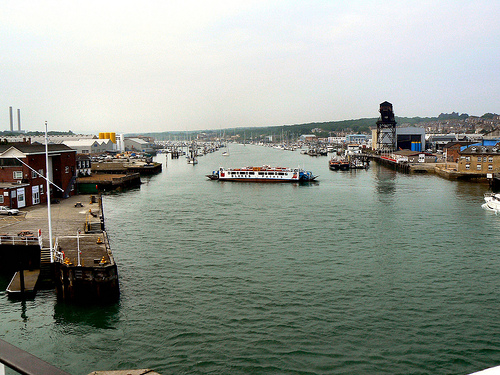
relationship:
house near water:
[0, 137, 93, 239] [199, 233, 423, 358]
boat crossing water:
[197, 145, 325, 204] [14, 133, 484, 368]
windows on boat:
[228, 169, 292, 183] [203, 161, 322, 188]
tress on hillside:
[436, 114, 488, 137] [264, 117, 434, 130]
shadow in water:
[373, 158, 398, 198] [199, 233, 423, 358]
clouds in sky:
[68, 22, 180, 55] [148, 31, 349, 90]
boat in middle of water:
[197, 145, 325, 204] [142, 191, 473, 343]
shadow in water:
[373, 160, 403, 192] [199, 233, 423, 358]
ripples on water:
[216, 257, 390, 345] [199, 233, 423, 358]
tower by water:
[360, 101, 409, 169] [199, 233, 423, 358]